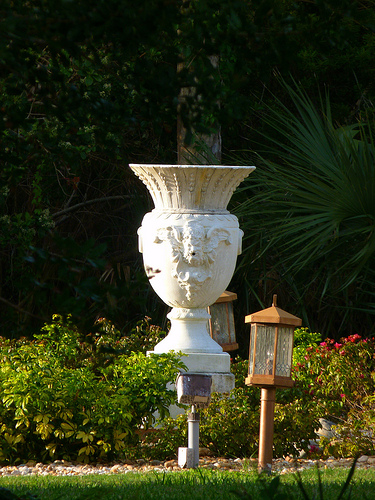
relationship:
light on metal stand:
[172, 370, 212, 469] [183, 408, 203, 466]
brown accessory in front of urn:
[241, 292, 306, 477] [127, 161, 258, 374]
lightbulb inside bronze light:
[212, 315, 221, 331] [206, 290, 238, 349]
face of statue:
[168, 224, 234, 295] [142, 155, 244, 347]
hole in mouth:
[188, 251, 196, 256] [113, 146, 312, 192]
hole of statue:
[188, 251, 196, 256] [129, 162, 256, 372]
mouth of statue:
[113, 146, 312, 192] [129, 162, 256, 372]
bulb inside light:
[266, 340, 285, 371] [245, 293, 301, 470]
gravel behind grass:
[1, 449, 193, 481] [201, 474, 270, 495]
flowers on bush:
[330, 332, 360, 347] [300, 331, 374, 401]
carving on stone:
[152, 218, 232, 306] [128, 161, 254, 369]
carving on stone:
[161, 217, 230, 319] [128, 161, 254, 369]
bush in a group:
[87, 352, 174, 461] [2, 309, 183, 459]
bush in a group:
[0, 312, 174, 461] [2, 309, 183, 459]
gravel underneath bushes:
[1, 449, 193, 481] [2, 312, 371, 462]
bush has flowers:
[296, 333, 374, 494] [291, 332, 375, 456]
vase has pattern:
[120, 161, 244, 362] [161, 218, 222, 296]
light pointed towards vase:
[172, 370, 212, 469] [127, 161, 256, 427]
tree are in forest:
[1, 0, 371, 325] [0, 2, 369, 162]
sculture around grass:
[128, 161, 258, 374] [8, 463, 334, 498]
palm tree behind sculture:
[179, 90, 374, 317] [128, 161, 258, 374]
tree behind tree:
[1, 0, 371, 325] [233, 72, 372, 301]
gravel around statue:
[1, 449, 193, 481] [125, 162, 257, 393]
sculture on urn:
[184, 226, 205, 269] [122, 154, 261, 390]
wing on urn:
[157, 223, 184, 262] [124, 154, 255, 429]